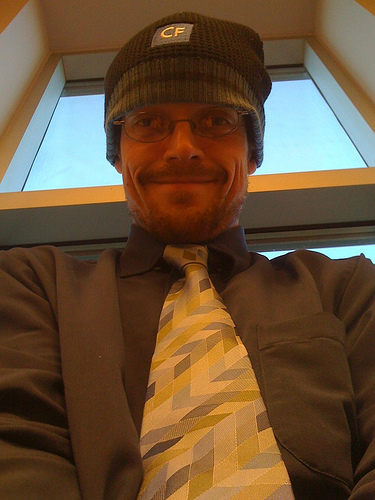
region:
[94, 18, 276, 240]
Hat on man's head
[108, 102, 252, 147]
A pair of glasses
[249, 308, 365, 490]
A pocket on a shirt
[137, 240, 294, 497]
A yellow, white and gray tie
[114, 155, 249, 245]
Facial hair on man's face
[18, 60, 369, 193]
A window behind the man's head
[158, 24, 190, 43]
"CF" written on a hat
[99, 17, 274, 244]
The man is smiling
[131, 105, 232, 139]
A pair of eyes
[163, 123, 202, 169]
Nose on man's face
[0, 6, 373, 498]
a man smiling at the camera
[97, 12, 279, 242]
the man is wearing a beanie cap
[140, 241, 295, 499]
man is wearing a multi-colored tie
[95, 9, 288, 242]
man is wearing eye glasses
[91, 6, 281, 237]
the man has facial hair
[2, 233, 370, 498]
the man is wearing a shirt and tie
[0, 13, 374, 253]
the window is behind the man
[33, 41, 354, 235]
the man is in front of the window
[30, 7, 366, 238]
the man is looking down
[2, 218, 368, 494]
the man is dressed up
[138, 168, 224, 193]
mouth of a person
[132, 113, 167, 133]
eye of a person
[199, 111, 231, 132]
eye of a person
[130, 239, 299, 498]
tie of a person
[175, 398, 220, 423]
chevron design on a tie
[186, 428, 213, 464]
chevron design on a tie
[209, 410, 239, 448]
chevron design on a tie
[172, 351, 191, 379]
chevron design on a tie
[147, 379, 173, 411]
chevron design on a tie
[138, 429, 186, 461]
chevron design on a tie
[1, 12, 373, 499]
man in brown shirt and multi colored tie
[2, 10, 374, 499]
man looking slightly down and smiling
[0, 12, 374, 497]
man wearing CF knit hat on head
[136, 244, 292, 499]
mans multi colored tie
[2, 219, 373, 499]
brown shirt the man is wearing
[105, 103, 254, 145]
eye glasses the man is wearing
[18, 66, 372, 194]
window above the mans head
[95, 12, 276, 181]
knit hat the man is wearing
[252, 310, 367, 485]
pocket of the mans shirt